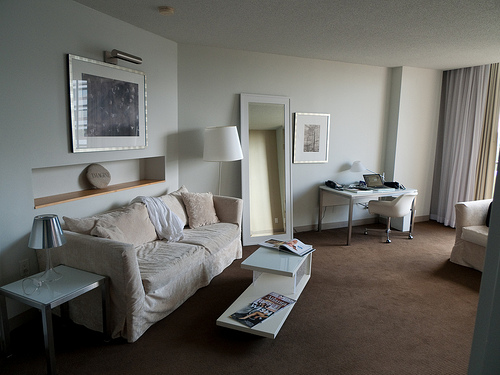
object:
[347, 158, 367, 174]
lamp shade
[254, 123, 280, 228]
reflection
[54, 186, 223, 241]
four cushions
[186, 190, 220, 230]
pillow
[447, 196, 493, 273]
couch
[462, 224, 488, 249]
cushion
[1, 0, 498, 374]
room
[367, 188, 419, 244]
chair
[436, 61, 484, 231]
curatin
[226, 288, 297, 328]
magazine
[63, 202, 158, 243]
cushion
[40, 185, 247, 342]
couch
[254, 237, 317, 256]
magazine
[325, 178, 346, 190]
telephone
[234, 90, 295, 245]
mirror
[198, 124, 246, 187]
lamp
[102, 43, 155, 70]
lamp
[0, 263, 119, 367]
end table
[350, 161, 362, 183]
lamp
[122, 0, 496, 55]
ceiling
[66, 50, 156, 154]
picture frame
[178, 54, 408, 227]
wall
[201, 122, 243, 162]
lampshade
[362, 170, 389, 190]
laptop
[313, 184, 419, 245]
desk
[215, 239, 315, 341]
coffee table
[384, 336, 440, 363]
carpet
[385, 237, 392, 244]
wheel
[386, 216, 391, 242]
leg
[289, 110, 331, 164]
frame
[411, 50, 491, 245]
window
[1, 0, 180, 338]
wall